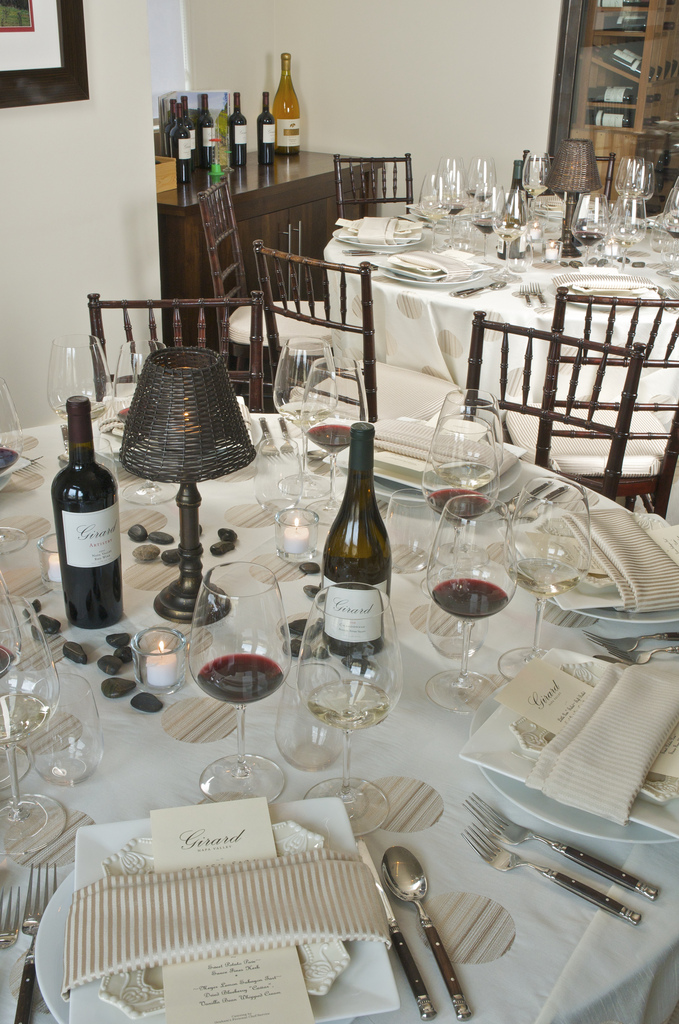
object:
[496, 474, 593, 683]
glass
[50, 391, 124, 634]
bottle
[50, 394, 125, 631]
wine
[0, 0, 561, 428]
wall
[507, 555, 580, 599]
wine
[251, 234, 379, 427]
chair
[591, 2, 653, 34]
shelves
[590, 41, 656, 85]
bottles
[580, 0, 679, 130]
glass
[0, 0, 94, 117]
painting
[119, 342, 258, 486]
lampshade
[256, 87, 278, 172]
wine bottles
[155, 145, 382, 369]
counter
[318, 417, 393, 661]
wine bottle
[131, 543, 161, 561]
stone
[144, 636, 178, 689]
candle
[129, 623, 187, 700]
holder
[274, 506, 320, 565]
holder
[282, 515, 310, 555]
candle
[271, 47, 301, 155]
bottle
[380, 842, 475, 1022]
spoon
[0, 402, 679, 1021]
table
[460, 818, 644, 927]
fork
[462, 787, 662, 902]
fork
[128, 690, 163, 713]
rock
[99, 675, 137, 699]
rock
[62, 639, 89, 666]
rock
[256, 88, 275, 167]
bottle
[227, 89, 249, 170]
bottle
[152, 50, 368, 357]
stand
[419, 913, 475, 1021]
handle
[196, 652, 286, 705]
wine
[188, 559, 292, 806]
glass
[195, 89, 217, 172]
bottle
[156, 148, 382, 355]
table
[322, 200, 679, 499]
table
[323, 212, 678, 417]
tablecloth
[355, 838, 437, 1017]
knife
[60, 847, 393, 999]
napkin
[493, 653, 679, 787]
menu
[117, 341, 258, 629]
lamp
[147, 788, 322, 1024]
invitation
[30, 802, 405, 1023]
plate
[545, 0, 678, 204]
wine rack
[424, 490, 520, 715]
wineglass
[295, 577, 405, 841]
wineglass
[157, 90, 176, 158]
book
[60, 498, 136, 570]
label